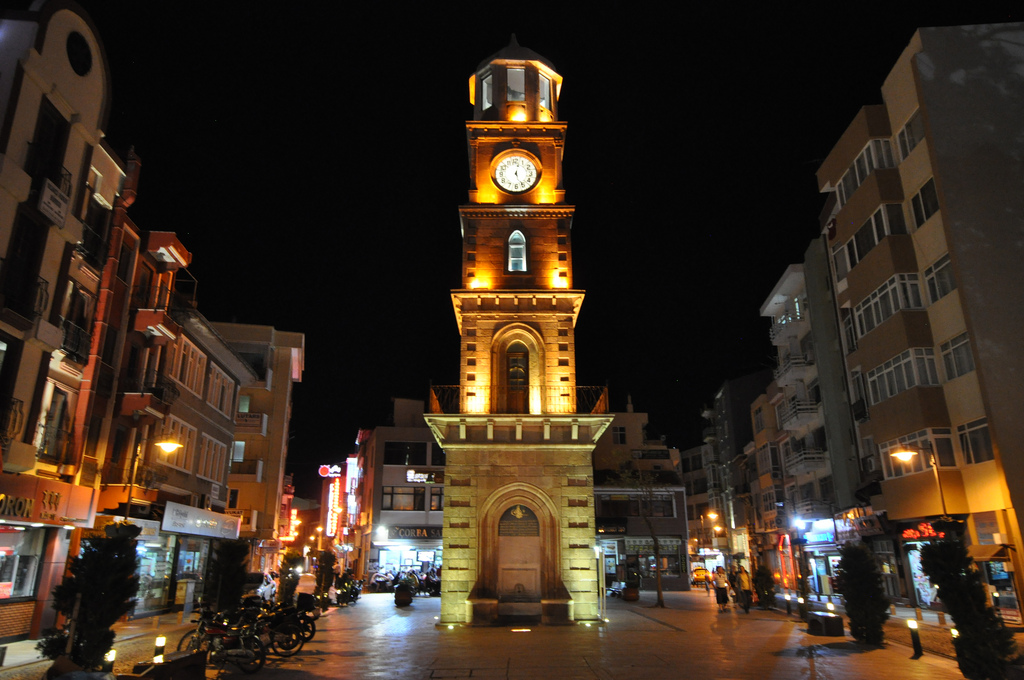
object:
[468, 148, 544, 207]
clock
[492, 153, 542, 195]
clock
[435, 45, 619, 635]
tower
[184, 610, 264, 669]
bike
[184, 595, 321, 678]
fence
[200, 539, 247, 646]
tree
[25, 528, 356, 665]
sidewalk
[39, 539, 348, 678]
sidewalk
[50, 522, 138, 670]
tree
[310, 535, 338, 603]
tree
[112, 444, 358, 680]
sidewalk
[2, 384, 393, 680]
sidewalk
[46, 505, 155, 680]
tree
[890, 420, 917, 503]
light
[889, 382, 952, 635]
pole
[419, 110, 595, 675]
lights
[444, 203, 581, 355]
tower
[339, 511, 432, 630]
lights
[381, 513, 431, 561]
blue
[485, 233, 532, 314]
window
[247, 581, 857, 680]
sidewalk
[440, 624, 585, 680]
rain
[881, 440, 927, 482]
light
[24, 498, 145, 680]
tree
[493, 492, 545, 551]
arch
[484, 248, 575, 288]
clock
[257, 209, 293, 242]
dark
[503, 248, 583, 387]
tower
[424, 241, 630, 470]
tower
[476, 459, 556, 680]
door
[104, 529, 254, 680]
door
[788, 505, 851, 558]
lights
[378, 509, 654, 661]
light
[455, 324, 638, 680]
tower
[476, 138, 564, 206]
face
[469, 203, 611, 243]
white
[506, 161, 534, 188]
hands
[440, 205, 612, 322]
color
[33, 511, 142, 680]
tree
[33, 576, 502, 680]
sidewalk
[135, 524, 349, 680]
bikes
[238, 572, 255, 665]
up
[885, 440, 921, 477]
light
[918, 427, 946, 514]
pole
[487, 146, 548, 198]
clock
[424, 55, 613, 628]
tower